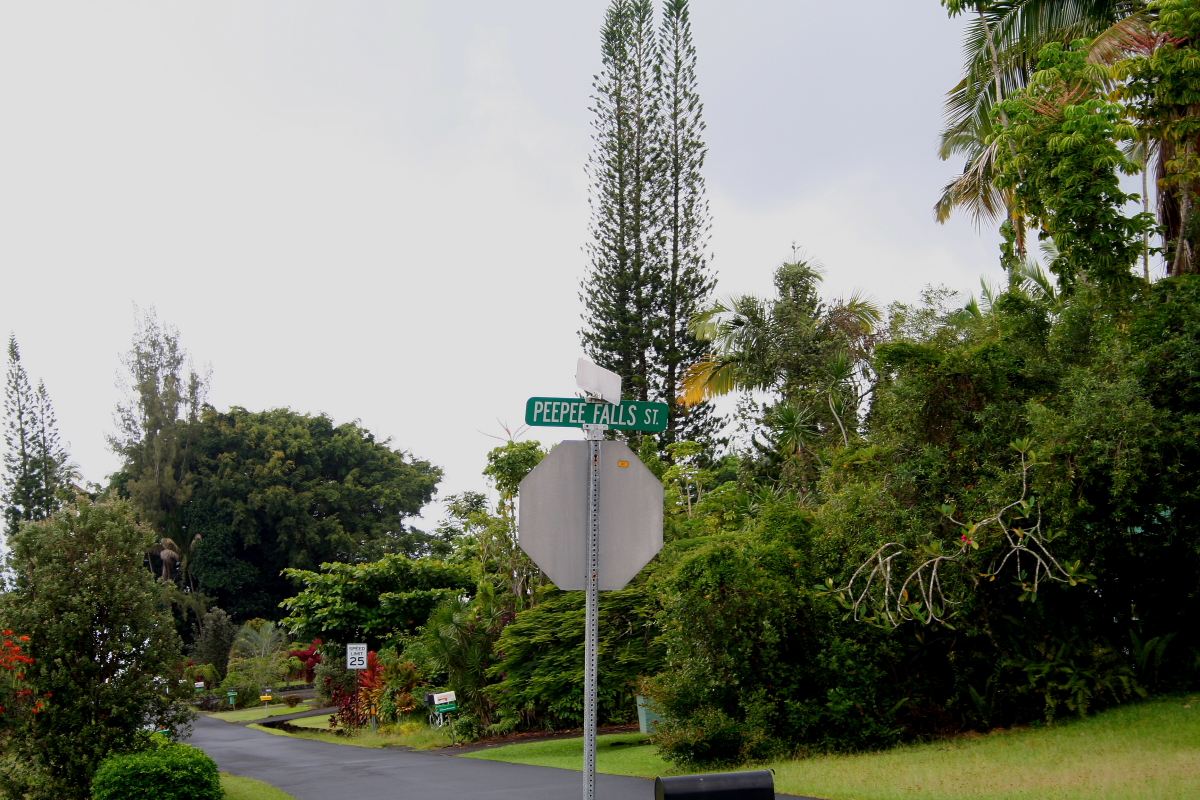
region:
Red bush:
[360, 645, 390, 720]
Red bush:
[288, 633, 325, 684]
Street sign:
[341, 634, 370, 718]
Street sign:
[432, 682, 462, 724]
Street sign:
[510, 436, 669, 796]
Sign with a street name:
[521, 393, 682, 432]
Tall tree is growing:
[579, 0, 712, 402]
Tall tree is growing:
[687, 252, 873, 505]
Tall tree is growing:
[111, 300, 219, 656]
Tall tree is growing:
[0, 333, 61, 653]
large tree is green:
[113, 412, 438, 612]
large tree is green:
[10, 486, 203, 789]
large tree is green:
[632, 481, 885, 751]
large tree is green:
[715, 271, 881, 454]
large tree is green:
[447, 441, 529, 600]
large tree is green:
[487, 597, 661, 737]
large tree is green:
[104, 304, 208, 537]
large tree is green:
[2, 331, 70, 528]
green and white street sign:
[525, 382, 677, 436]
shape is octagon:
[496, 440, 679, 594]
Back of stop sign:
[488, 433, 680, 614]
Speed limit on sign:
[335, 629, 386, 721]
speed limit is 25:
[337, 637, 385, 721]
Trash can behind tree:
[623, 675, 664, 736]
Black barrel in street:
[640, 759, 785, 796]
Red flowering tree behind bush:
[285, 631, 327, 692]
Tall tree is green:
[582, 0, 708, 478]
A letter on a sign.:
[534, 397, 547, 419]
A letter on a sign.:
[544, 397, 554, 421]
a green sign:
[520, 391, 674, 435]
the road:
[371, 741, 422, 782]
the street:
[333, 746, 411, 790]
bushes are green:
[700, 561, 802, 694]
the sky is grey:
[270, 173, 414, 263]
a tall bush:
[602, 12, 711, 366]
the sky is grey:
[794, 117, 917, 238]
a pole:
[578, 600, 627, 783]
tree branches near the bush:
[847, 526, 1015, 622]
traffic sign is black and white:
[338, 633, 370, 693]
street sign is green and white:
[523, 393, 680, 435]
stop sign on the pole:
[515, 432, 689, 600]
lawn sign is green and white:
[424, 682, 463, 714]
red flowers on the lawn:
[357, 655, 386, 691]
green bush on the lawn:
[78, 722, 222, 797]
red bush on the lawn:
[290, 629, 326, 701]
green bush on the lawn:
[484, 571, 677, 740]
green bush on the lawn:
[7, 475, 197, 778]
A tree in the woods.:
[595, 6, 672, 427]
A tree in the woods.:
[729, 267, 854, 441]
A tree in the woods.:
[772, 394, 856, 503]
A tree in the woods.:
[674, 521, 824, 704]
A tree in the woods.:
[112, 385, 436, 599]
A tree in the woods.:
[83, 306, 228, 551]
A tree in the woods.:
[0, 337, 51, 529]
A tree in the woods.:
[652, 6, 710, 467]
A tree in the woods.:
[940, 53, 1053, 323]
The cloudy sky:
[6, 161, 1185, 488]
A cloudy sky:
[7, 170, 1186, 442]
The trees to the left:
[4, 482, 230, 790]